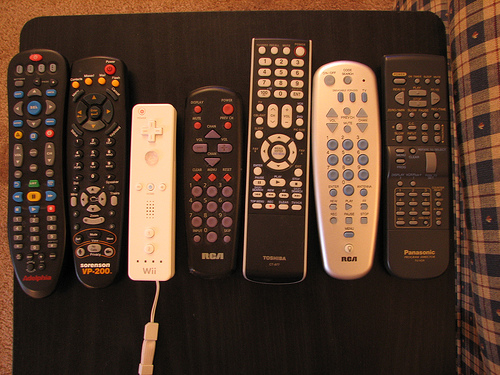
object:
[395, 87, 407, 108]
button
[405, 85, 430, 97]
button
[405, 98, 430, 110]
button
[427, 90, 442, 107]
button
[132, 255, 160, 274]
lettering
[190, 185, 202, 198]
button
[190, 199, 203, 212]
button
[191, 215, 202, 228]
button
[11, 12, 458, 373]
table top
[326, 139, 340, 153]
button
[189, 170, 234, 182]
row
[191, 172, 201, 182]
button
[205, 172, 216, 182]
button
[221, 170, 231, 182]
button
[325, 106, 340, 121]
button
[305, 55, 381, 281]
remote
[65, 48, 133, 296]
controller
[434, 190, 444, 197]
button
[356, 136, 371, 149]
button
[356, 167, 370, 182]
button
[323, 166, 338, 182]
button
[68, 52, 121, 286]
remote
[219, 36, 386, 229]
buttons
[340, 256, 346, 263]
black letter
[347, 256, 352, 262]
black letter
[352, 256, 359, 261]
black letter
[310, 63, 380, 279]
controller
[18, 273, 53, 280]
lettering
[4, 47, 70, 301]
controller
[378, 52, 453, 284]
controller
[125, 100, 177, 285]
controller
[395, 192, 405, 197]
button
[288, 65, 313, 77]
button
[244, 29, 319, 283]
controller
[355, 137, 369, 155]
button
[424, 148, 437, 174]
button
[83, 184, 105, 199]
button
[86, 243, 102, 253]
button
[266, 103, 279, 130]
button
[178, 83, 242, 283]
controller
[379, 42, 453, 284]
remote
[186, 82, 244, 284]
remote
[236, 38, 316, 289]
remote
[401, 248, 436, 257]
lettering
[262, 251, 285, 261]
lettering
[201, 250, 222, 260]
lettering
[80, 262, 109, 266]
lettering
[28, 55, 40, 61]
lettering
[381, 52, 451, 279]
remote